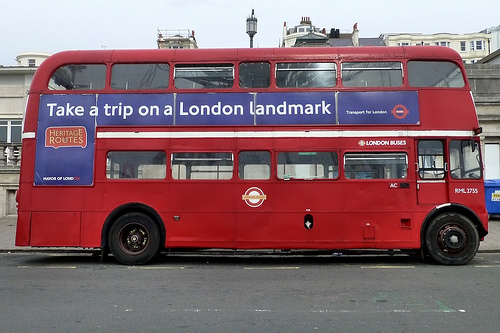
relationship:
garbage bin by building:
[484, 176, 497, 217] [16, 16, 500, 249]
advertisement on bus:
[35, 91, 419, 198] [21, 53, 495, 261]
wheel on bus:
[419, 206, 480, 264] [21, 53, 495, 261]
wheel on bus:
[105, 209, 163, 259] [21, 53, 495, 261]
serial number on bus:
[452, 184, 481, 194] [36, 45, 486, 271]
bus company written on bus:
[350, 126, 410, 153] [21, 53, 495, 261]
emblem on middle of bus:
[237, 184, 269, 213] [36, 45, 486, 271]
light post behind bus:
[244, 4, 267, 49] [21, 53, 495, 261]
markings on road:
[106, 295, 484, 316] [2, 255, 498, 331]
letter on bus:
[44, 95, 58, 116] [4, 35, 494, 264]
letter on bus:
[55, 99, 69, 119] [36, 45, 486, 271]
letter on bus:
[64, 94, 76, 121] [21, 53, 495, 261]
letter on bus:
[86, 104, 107, 120] [21, 53, 495, 261]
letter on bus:
[88, 99, 104, 122] [36, 45, 486, 271]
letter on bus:
[101, 103, 117, 121] [4, 35, 494, 264]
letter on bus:
[104, 101, 124, 117] [21, 53, 495, 261]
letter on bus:
[121, 101, 142, 119] [36, 45, 486, 271]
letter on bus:
[119, 103, 135, 128] [21, 53, 495, 261]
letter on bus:
[133, 95, 147, 116] [21, 53, 495, 261]